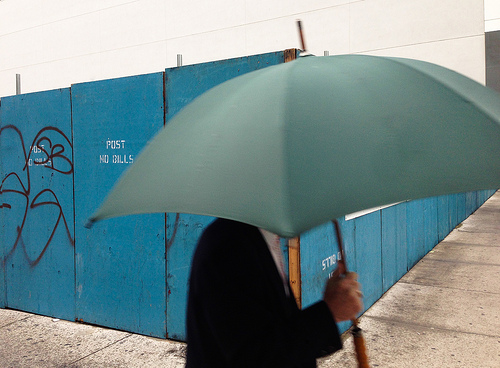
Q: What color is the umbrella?
A: Green.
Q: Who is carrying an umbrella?
A: A man.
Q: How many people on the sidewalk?
A: One.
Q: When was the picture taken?
A: Daytime.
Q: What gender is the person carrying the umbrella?
A: Male.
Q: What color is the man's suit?
A: Black.